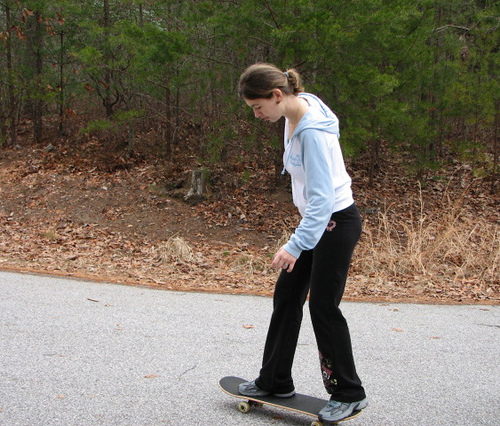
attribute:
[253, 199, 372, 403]
pants — Black 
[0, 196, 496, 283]
grass — dry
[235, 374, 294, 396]
right shoe — dark gray, light gray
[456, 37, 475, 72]
nest — wasp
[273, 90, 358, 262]
sweater — White 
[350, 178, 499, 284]
grass — dry, dead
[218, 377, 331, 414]
paper — black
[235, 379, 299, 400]
shoe — gray 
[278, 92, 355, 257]
jacket — light blue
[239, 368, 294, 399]
shoe — gray, dark gray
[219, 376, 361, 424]
skateboard — grey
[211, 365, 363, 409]
skateboard — black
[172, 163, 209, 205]
stump — dried, decrepit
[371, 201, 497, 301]
grass — brown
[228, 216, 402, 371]
pants — floral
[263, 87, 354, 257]
shirt — blue